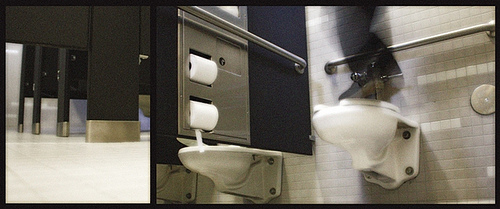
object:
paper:
[179, 99, 225, 143]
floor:
[3, 113, 148, 202]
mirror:
[4, 5, 150, 205]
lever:
[382, 72, 404, 80]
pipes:
[350, 54, 405, 98]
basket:
[176, 40, 237, 91]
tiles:
[265, 4, 496, 204]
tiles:
[195, 171, 253, 203]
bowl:
[311, 102, 413, 169]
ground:
[426, 120, 451, 142]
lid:
[451, 74, 496, 114]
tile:
[3, 40, 148, 207]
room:
[3, 5, 148, 205]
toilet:
[177, 141, 288, 203]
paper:
[183, 50, 222, 90]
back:
[306, 5, 491, 101]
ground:
[421, 165, 449, 178]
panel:
[397, 129, 414, 171]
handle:
[185, 7, 307, 73]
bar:
[320, 17, 495, 74]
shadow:
[326, 5, 383, 57]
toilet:
[305, 95, 425, 192]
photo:
[158, 1, 494, 203]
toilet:
[159, 168, 196, 203]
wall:
[193, 7, 494, 202]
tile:
[23, 162, 142, 198]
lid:
[307, 92, 402, 118]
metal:
[350, 53, 405, 103]